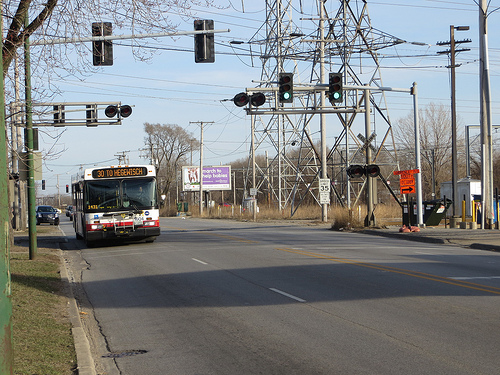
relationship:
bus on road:
[70, 163, 181, 247] [177, 219, 334, 346]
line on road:
[259, 281, 311, 318] [177, 219, 334, 346]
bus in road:
[70, 163, 181, 247] [177, 219, 334, 346]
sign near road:
[390, 166, 431, 197] [177, 219, 334, 346]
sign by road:
[390, 166, 431, 197] [177, 219, 334, 346]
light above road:
[272, 65, 303, 114] [177, 219, 334, 346]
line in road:
[259, 281, 311, 318] [177, 219, 334, 346]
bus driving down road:
[79, 158, 181, 248] [79, 219, 500, 374]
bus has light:
[88, 150, 183, 263] [272, 65, 303, 114]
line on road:
[266, 284, 307, 305] [188, 260, 338, 357]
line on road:
[359, 250, 438, 299] [224, 219, 465, 342]